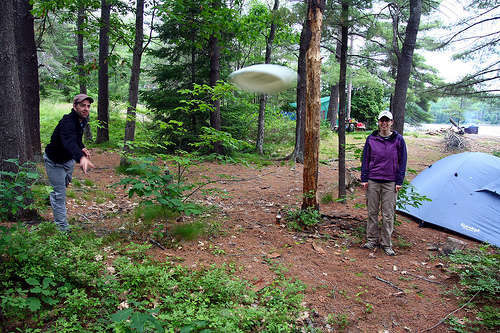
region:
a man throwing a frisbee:
[44, 73, 109, 240]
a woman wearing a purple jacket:
[361, 104, 418, 268]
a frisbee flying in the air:
[211, 54, 324, 103]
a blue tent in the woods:
[407, 154, 497, 240]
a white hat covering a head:
[379, 97, 393, 122]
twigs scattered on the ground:
[374, 261, 452, 301]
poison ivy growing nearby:
[30, 251, 78, 311]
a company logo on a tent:
[459, 215, 479, 237]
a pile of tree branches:
[433, 120, 477, 152]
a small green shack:
[320, 95, 331, 120]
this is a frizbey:
[236, 67, 288, 94]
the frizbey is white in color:
[233, 67, 296, 98]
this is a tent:
[421, 153, 499, 240]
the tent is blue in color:
[437, 155, 490, 237]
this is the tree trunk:
[300, 55, 327, 197]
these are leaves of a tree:
[167, 6, 270, 38]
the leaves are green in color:
[171, 66, 209, 135]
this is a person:
[48, 88, 101, 218]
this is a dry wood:
[441, 122, 466, 152]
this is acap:
[61, 87, 98, 103]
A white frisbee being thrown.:
[222, 57, 297, 106]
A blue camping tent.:
[396, 144, 498, 253]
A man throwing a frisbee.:
[38, 76, 97, 249]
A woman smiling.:
[354, 105, 412, 259]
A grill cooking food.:
[443, 108, 486, 145]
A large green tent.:
[287, 89, 354, 138]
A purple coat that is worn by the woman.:
[354, 126, 413, 188]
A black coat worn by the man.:
[44, 110, 101, 173]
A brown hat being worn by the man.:
[64, 87, 97, 112]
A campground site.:
[65, 126, 493, 324]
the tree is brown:
[286, 21, 350, 226]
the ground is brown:
[221, 159, 303, 271]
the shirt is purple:
[357, 130, 412, 183]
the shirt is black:
[37, 108, 109, 166]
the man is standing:
[351, 97, 419, 262]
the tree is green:
[187, 14, 294, 164]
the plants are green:
[137, 82, 230, 254]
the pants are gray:
[29, 154, 90, 231]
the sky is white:
[422, 0, 483, 97]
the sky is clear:
[435, 1, 483, 91]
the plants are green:
[160, 70, 248, 173]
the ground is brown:
[234, 205, 316, 284]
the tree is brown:
[230, 9, 364, 212]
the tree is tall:
[273, 5, 342, 247]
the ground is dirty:
[238, 192, 403, 289]